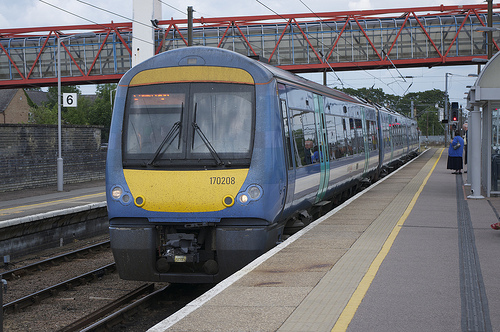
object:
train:
[105, 44, 433, 286]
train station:
[0, 1, 500, 332]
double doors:
[311, 99, 333, 200]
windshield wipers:
[184, 105, 238, 170]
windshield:
[131, 89, 247, 172]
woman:
[439, 120, 471, 174]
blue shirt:
[449, 138, 467, 155]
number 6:
[65, 91, 79, 104]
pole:
[53, 30, 66, 191]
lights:
[59, 30, 97, 44]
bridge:
[0, 6, 500, 91]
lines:
[151, 139, 451, 331]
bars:
[0, 3, 500, 86]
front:
[103, 47, 282, 280]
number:
[203, 172, 247, 189]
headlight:
[231, 180, 263, 208]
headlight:
[104, 181, 130, 203]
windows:
[282, 104, 324, 161]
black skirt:
[446, 157, 462, 168]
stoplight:
[449, 100, 464, 122]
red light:
[437, 115, 462, 119]